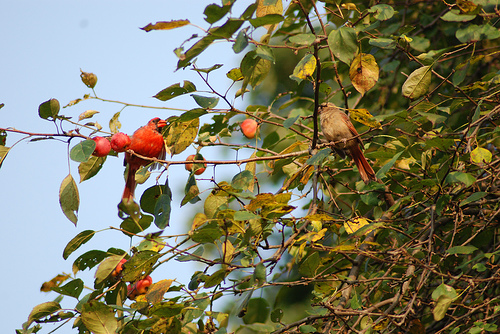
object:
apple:
[239, 117, 258, 139]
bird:
[315, 101, 377, 186]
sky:
[2, 2, 143, 69]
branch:
[2, 124, 368, 167]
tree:
[257, 0, 500, 333]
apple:
[91, 136, 110, 157]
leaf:
[350, 50, 382, 96]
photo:
[0, 0, 500, 334]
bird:
[118, 116, 168, 205]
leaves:
[135, 17, 196, 34]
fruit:
[111, 131, 131, 152]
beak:
[157, 119, 167, 127]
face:
[150, 116, 162, 131]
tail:
[349, 149, 376, 182]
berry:
[136, 280, 151, 294]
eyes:
[151, 119, 156, 124]